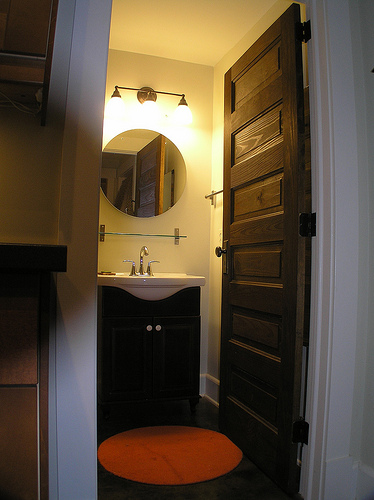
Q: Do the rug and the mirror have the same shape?
A: Yes, both the rug and the mirror are round.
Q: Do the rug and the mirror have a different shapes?
A: No, both the rug and the mirror are round.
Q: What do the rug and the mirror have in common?
A: The shape, both the rug and the mirror are round.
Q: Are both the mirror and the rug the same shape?
A: Yes, both the mirror and the rug are round.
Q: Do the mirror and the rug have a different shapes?
A: No, both the mirror and the rug are round.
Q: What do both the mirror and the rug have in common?
A: The shape, both the mirror and the rug are round.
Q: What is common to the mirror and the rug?
A: The shape, both the mirror and the rug are round.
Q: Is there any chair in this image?
A: No, there are no chairs.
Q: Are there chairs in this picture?
A: No, there are no chairs.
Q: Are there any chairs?
A: No, there are no chairs.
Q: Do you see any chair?
A: No, there are no chairs.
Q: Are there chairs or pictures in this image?
A: No, there are no chairs or pictures.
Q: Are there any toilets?
A: No, there are no toilets.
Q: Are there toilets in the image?
A: No, there are no toilets.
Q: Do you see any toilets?
A: No, there are no toilets.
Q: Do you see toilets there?
A: No, there are no toilets.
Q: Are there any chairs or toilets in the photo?
A: No, there are no toilets or chairs.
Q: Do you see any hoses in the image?
A: No, there are no hoses.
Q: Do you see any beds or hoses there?
A: No, there are no hoses or beds.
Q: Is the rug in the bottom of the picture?
A: Yes, the rug is in the bottom of the image.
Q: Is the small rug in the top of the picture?
A: No, the rug is in the bottom of the image.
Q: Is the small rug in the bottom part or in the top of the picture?
A: The rug is in the bottom of the image.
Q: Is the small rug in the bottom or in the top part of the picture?
A: The rug is in the bottom of the image.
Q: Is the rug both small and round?
A: Yes, the rug is small and round.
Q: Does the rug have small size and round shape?
A: Yes, the rug is small and round.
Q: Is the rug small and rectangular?
A: No, the rug is small but round.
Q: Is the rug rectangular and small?
A: No, the rug is small but round.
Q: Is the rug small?
A: Yes, the rug is small.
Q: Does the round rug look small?
A: Yes, the rug is small.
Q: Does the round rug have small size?
A: Yes, the rug is small.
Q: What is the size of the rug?
A: The rug is small.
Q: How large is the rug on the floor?
A: The rug is small.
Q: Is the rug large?
A: No, the rug is small.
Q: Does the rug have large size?
A: No, the rug is small.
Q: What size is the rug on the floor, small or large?
A: The rug is small.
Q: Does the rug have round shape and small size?
A: Yes, the rug is round and small.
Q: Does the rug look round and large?
A: No, the rug is round but small.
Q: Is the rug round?
A: Yes, the rug is round.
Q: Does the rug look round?
A: Yes, the rug is round.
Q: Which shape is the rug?
A: The rug is round.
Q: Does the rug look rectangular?
A: No, the rug is round.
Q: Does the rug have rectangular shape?
A: No, the rug is round.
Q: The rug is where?
A: The rug is on the floor.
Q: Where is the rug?
A: The rug is on the floor.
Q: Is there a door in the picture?
A: Yes, there is a door.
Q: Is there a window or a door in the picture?
A: Yes, there is a door.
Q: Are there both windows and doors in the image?
A: No, there is a door but no windows.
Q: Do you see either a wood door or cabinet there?
A: Yes, there is a wood door.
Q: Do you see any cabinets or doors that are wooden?
A: Yes, the door is wooden.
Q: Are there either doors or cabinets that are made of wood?
A: Yes, the door is made of wood.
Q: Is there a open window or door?
A: Yes, there is an open door.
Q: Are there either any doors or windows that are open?
A: Yes, the door is open.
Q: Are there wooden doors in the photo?
A: Yes, there is a wood door.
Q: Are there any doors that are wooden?
A: Yes, there is a door that is wooden.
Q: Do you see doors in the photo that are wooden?
A: Yes, there is a door that is wooden.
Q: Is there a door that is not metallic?
A: Yes, there is a wooden door.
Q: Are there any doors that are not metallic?
A: Yes, there is a wooden door.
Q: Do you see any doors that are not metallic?
A: Yes, there is a wooden door.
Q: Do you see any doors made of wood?
A: Yes, there is a door that is made of wood.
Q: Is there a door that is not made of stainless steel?
A: Yes, there is a door that is made of wood.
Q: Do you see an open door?
A: Yes, there is an open door.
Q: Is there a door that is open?
A: Yes, there is a door that is open.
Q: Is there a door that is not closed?
A: Yes, there is a open door.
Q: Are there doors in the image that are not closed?
A: Yes, there is a open door.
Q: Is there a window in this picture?
A: No, there are no windows.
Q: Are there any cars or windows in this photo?
A: No, there are no windows or cars.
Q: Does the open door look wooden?
A: Yes, the door is wooden.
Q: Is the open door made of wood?
A: Yes, the door is made of wood.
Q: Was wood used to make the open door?
A: Yes, the door is made of wood.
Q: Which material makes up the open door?
A: The door is made of wood.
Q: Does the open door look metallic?
A: No, the door is wooden.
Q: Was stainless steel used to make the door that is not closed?
A: No, the door is made of wood.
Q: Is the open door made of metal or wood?
A: The door is made of wood.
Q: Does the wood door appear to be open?
A: Yes, the door is open.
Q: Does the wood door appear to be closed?
A: No, the door is open.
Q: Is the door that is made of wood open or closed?
A: The door is open.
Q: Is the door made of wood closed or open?
A: The door is open.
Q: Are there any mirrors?
A: Yes, there is a mirror.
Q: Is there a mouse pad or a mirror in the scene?
A: Yes, there is a mirror.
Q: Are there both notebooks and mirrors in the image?
A: No, there is a mirror but no notebooks.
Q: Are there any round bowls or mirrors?
A: Yes, there is a round mirror.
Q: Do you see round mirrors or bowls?
A: Yes, there is a round mirror.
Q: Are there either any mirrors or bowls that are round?
A: Yes, the mirror is round.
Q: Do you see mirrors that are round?
A: Yes, there is a round mirror.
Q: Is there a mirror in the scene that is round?
A: Yes, there is a mirror that is round.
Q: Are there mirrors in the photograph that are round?
A: Yes, there is a mirror that is round.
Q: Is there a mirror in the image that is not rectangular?
A: Yes, there is a round mirror.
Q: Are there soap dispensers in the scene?
A: No, there are no soap dispensers.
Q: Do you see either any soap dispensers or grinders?
A: No, there are no soap dispensers or grinders.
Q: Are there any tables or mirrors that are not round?
A: No, there is a mirror but it is round.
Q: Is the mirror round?
A: Yes, the mirror is round.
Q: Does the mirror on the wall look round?
A: Yes, the mirror is round.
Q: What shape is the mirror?
A: The mirror is round.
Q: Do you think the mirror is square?
A: No, the mirror is round.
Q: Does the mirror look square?
A: No, the mirror is round.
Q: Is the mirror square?
A: No, the mirror is round.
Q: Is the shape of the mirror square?
A: No, the mirror is round.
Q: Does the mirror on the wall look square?
A: No, the mirror is round.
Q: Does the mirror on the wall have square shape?
A: No, the mirror is round.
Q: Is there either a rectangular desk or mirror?
A: No, there is a mirror but it is round.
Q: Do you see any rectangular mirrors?
A: No, there is a mirror but it is round.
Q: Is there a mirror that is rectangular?
A: No, there is a mirror but it is round.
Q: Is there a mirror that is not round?
A: No, there is a mirror but it is round.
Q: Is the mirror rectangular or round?
A: The mirror is round.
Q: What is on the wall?
A: The mirror is on the wall.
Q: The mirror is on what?
A: The mirror is on the wall.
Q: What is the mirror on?
A: The mirror is on the wall.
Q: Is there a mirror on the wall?
A: Yes, there is a mirror on the wall.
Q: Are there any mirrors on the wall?
A: Yes, there is a mirror on the wall.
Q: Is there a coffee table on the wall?
A: No, there is a mirror on the wall.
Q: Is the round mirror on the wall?
A: Yes, the mirror is on the wall.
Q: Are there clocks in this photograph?
A: No, there are no clocks.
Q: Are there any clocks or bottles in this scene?
A: No, there are no clocks or bottles.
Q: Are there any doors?
A: Yes, there are doors.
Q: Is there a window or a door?
A: Yes, there are doors.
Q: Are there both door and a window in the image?
A: No, there are doors but no windows.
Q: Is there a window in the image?
A: No, there are no windows.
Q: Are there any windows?
A: No, there are no windows.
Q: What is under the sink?
A: The doors are under the sink.